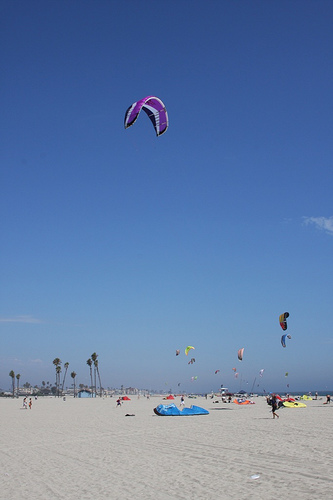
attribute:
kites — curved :
[168, 302, 298, 379]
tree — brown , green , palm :
[90, 351, 99, 399]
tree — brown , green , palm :
[84, 355, 94, 398]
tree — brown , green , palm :
[68, 368, 77, 397]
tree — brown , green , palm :
[6, 366, 15, 397]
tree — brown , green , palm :
[49, 354, 60, 394]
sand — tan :
[1, 393, 332, 425]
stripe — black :
[125, 93, 164, 133]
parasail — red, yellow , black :
[260, 307, 299, 337]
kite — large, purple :
[120, 92, 172, 150]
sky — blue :
[86, 211, 174, 251]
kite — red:
[121, 395, 132, 400]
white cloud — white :
[298, 212, 332, 234]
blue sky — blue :
[1, 0, 332, 391]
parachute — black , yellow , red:
[278, 311, 290, 330]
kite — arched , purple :
[103, 72, 195, 142]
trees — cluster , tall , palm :
[55, 363, 61, 397]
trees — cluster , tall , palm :
[51, 355, 62, 397]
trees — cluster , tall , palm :
[59, 359, 71, 396]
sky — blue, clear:
[22, 4, 331, 76]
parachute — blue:
[100, 67, 197, 155]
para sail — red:
[117, 91, 169, 141]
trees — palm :
[41, 358, 130, 393]